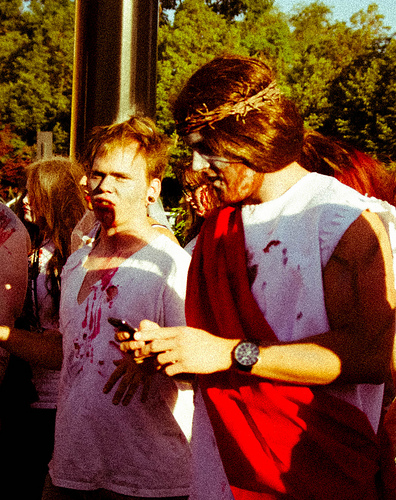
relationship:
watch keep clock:
[187, 342, 277, 418] [233, 341, 260, 369]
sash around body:
[190, 207, 393, 498] [173, 175, 394, 494]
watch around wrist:
[230, 338, 260, 373] [222, 337, 232, 375]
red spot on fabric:
[263, 238, 282, 252] [236, 171, 384, 426]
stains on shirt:
[81, 298, 102, 334] [43, 235, 194, 497]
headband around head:
[174, 78, 282, 136] [172, 55, 303, 203]